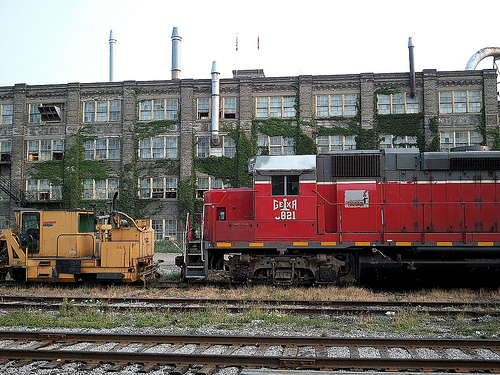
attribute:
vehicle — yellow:
[0, 208, 161, 285]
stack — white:
[172, 27, 181, 81]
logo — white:
[246, 187, 346, 244]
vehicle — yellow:
[7, 174, 169, 314]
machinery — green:
[3, 195, 167, 291]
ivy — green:
[28, 92, 440, 258]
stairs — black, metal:
[175, 198, 220, 291]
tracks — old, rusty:
[79, 240, 499, 372]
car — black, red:
[202, 141, 499, 325]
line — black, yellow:
[473, 236, 498, 247]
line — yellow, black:
[429, 236, 460, 252]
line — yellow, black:
[391, 240, 411, 248]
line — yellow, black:
[353, 239, 374, 248]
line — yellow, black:
[315, 239, 340, 249]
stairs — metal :
[186, 233, 211, 272]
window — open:
[222, 98, 235, 120]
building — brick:
[2, 65, 499, 252]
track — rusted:
[435, 323, 486, 370]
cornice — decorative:
[2, 72, 485, 101]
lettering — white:
[268, 201, 300, 224]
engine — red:
[180, 156, 347, 288]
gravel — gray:
[1, 296, 485, 373]